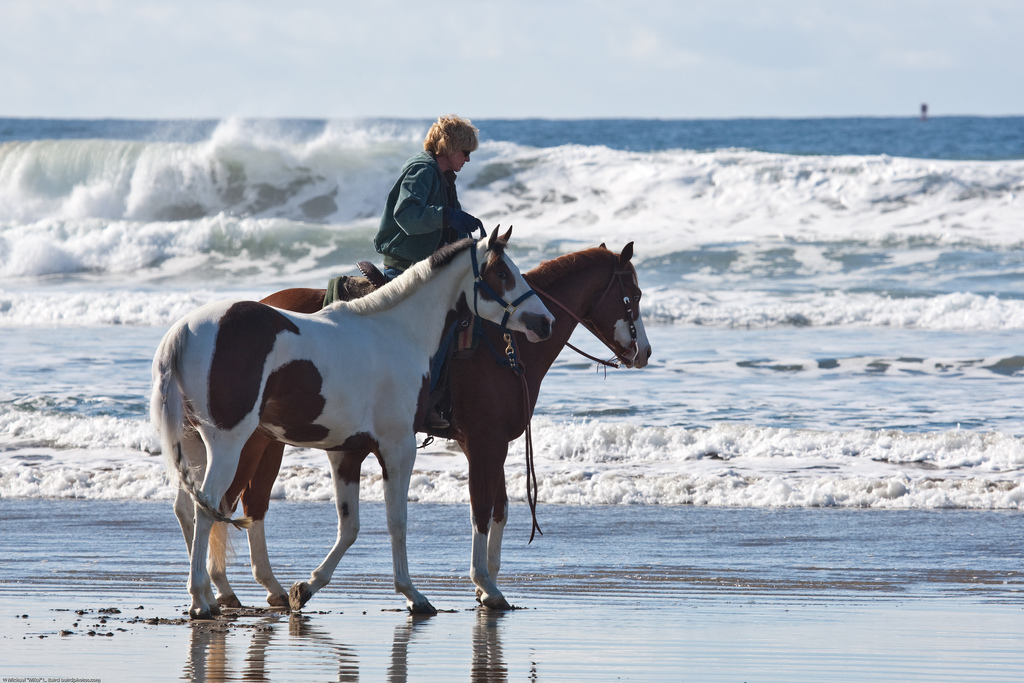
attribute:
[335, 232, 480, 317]
mane — white, brown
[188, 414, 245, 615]
legs — back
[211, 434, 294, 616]
legs — back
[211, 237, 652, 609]
horse — dark, brown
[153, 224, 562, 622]
horse — white, brown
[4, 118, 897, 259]
waves — high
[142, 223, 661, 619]
two horses — standing side by side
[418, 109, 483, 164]
blond hair — short